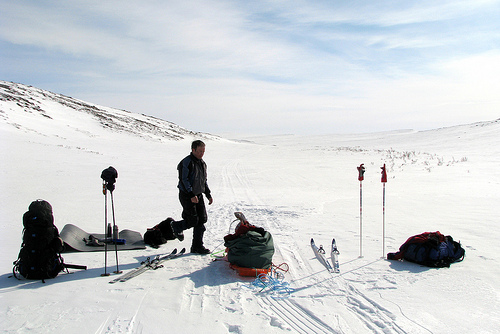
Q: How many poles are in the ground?
A: 4.